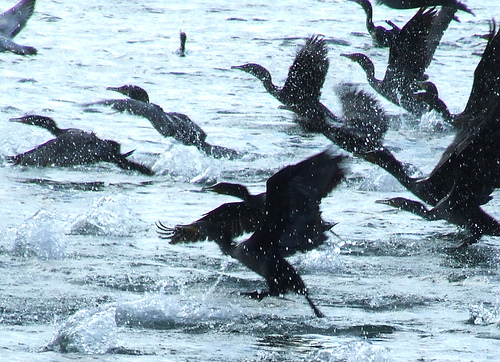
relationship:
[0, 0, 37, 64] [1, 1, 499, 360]
bird over water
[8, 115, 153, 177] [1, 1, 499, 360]
bird over water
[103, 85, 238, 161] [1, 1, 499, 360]
bird over water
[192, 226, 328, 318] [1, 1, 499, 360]
bird over water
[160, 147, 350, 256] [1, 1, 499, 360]
bird over water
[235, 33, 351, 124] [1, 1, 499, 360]
bird over water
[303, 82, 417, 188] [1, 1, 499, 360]
bird over water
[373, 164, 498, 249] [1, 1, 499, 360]
bird over water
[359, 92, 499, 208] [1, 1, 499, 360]
bird over water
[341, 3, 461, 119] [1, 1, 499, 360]
bird over water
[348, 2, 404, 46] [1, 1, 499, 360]
bird over water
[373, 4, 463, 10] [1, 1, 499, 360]
bird over water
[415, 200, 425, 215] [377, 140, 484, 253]
droplets landing on bird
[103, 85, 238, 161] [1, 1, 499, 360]
bird splashing in water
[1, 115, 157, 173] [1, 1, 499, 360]
bird splashing in water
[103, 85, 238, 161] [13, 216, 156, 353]
bird playing in a river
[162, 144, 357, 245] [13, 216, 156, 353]
bird playing in a river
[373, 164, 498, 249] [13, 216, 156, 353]
bird playing in a river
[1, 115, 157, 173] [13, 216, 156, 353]
bird playing in a river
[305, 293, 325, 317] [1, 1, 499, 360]
feather fanning water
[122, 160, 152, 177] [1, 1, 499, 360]
feather fanning water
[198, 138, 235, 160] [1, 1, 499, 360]
feather fanning water